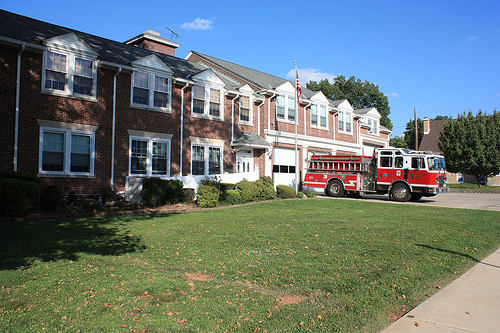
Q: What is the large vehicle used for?
A: Fighting fires.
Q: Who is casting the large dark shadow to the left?
A: A tree.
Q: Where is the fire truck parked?
A: In front of a fire house.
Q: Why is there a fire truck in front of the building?
A: For firefighters to use when putting out fires.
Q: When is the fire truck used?
A: When there is an emergency.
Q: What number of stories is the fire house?
A: 2.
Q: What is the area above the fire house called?
A: Sky.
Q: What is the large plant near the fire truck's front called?
A: A tree.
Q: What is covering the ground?
A: Grass.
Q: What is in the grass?
A: Leaves.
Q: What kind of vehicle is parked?
A: Fire truck.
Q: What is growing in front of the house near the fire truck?
A: Bushes.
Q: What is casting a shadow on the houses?
A: Tree.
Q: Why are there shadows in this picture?
A: It is daytime.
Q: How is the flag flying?
A: Full mast.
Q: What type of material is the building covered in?
A: Bricks.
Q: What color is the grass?
A: Green.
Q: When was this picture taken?
A: Daytime.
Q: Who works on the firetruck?
A: Firefighters.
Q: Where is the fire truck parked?
A: In front of the building.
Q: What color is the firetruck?
A: Red.